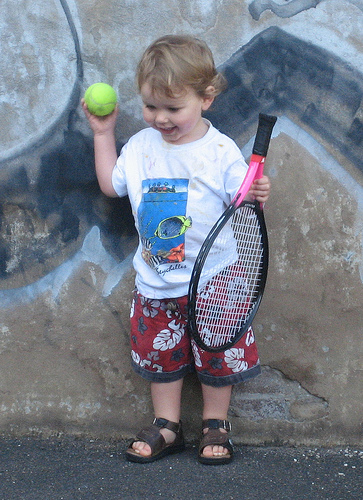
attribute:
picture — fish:
[127, 172, 194, 274]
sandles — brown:
[111, 413, 244, 465]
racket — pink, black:
[173, 90, 308, 347]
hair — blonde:
[139, 37, 222, 91]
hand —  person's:
[253, 176, 270, 206]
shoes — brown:
[124, 417, 234, 464]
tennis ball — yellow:
[82, 81, 118, 115]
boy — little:
[73, 32, 272, 465]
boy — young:
[94, 49, 307, 376]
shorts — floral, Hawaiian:
[126, 256, 263, 388]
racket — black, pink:
[208, 120, 294, 335]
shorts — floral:
[127, 295, 261, 383]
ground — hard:
[1, 440, 360, 498]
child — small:
[80, 31, 272, 463]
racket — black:
[185, 111, 276, 352]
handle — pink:
[251, 112, 277, 157]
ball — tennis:
[74, 78, 127, 118]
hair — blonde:
[137, 41, 216, 91]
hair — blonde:
[117, 27, 234, 150]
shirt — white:
[111, 116, 250, 298]